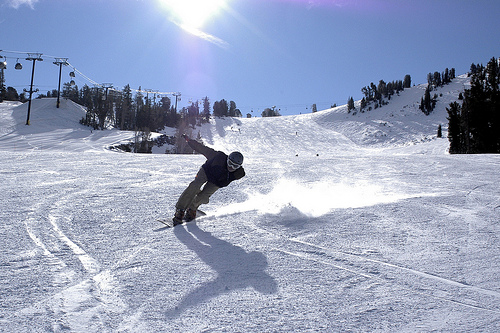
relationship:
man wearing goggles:
[153, 126, 249, 243] [225, 159, 239, 172]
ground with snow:
[37, 191, 254, 314] [271, 237, 359, 311]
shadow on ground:
[165, 221, 281, 314] [37, 191, 254, 314]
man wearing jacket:
[153, 126, 249, 243] [204, 157, 237, 197]